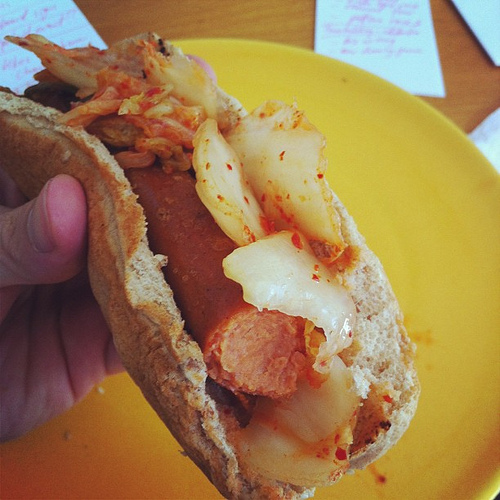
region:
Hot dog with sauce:
[1, 19, 429, 498]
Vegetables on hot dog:
[46, 33, 373, 333]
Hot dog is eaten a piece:
[153, 164, 328, 402]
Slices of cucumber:
[146, 96, 381, 351]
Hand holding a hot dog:
[1, 31, 428, 498]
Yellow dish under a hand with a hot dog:
[16, 31, 497, 498]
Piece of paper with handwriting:
[302, 0, 457, 100]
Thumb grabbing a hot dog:
[3, 166, 128, 300]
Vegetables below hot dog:
[235, 375, 360, 482]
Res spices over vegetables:
[243, 187, 308, 257]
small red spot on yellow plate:
[368, 465, 416, 485]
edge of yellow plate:
[427, 110, 474, 132]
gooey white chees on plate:
[238, 247, 306, 302]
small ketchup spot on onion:
[273, 140, 307, 167]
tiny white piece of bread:
[144, 248, 184, 282]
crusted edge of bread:
[123, 300, 212, 446]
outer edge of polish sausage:
[187, 313, 255, 365]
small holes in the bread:
[360, 311, 399, 341]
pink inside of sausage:
[233, 330, 298, 380]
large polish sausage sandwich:
[39, 94, 418, 493]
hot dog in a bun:
[29, 29, 416, 478]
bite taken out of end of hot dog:
[191, 299, 317, 404]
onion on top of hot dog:
[220, 219, 355, 337]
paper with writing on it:
[304, 5, 454, 72]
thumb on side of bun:
[20, 162, 95, 292]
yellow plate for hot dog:
[195, 26, 496, 229]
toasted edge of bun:
[103, 154, 158, 288]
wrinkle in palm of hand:
[25, 280, 89, 386]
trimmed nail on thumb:
[20, 174, 57, 265]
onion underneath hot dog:
[238, 391, 330, 451]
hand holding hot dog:
[1, 162, 132, 447]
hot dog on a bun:
[105, 145, 314, 405]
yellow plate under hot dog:
[1, 37, 498, 498]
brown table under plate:
[74, 0, 499, 134]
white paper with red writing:
[312, 0, 449, 100]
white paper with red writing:
[1, 0, 108, 92]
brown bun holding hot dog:
[1, 55, 421, 497]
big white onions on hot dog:
[226, 361, 362, 494]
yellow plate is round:
[1, 38, 497, 498]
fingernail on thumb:
[26, 175, 57, 256]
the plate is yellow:
[371, 122, 482, 272]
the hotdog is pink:
[143, 190, 336, 407]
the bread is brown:
[87, 208, 204, 406]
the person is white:
[0, 178, 167, 459]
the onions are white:
[181, 96, 366, 296]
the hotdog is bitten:
[112, 227, 452, 497]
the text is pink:
[337, 1, 433, 81]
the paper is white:
[317, 2, 462, 104]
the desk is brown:
[200, 5, 298, 32]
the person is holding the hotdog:
[18, 68, 403, 423]